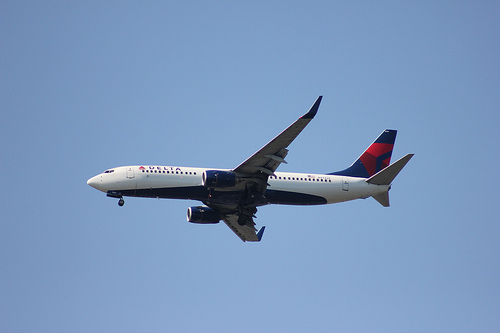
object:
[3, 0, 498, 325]
sky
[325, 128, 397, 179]
tail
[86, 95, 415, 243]
airplane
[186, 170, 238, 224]
engines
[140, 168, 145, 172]
windows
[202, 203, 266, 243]
wings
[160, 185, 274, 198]
underside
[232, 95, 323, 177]
airplane wings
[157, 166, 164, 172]
letter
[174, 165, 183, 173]
letter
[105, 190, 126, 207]
front wheel